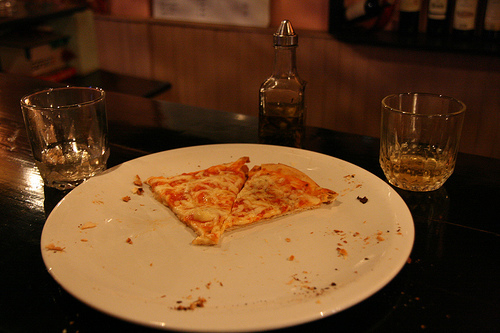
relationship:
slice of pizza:
[232, 159, 328, 229] [144, 153, 341, 247]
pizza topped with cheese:
[144, 153, 341, 247] [170, 181, 237, 222]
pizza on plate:
[144, 153, 341, 247] [31, 138, 420, 329]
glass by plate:
[359, 82, 475, 197] [31, 138, 420, 329]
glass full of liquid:
[359, 82, 475, 197] [379, 149, 456, 191]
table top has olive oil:
[4, 114, 499, 325] [255, 20, 314, 152]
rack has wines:
[331, 1, 498, 62] [342, 2, 500, 35]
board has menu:
[145, 3, 281, 36] [156, 2, 268, 22]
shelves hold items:
[13, 4, 167, 101] [5, 27, 85, 82]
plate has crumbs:
[31, 138, 420, 329] [285, 218, 362, 284]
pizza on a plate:
[144, 153, 341, 247] [31, 138, 420, 329]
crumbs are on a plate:
[285, 218, 362, 284] [31, 138, 420, 329]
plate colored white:
[31, 138, 420, 329] [102, 245, 163, 301]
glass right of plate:
[359, 82, 475, 197] [31, 138, 420, 329]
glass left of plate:
[20, 88, 118, 197] [31, 138, 420, 329]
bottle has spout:
[255, 20, 314, 152] [270, 21, 300, 46]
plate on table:
[31, 138, 420, 329] [4, 114, 499, 325]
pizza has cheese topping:
[144, 153, 341, 247] [170, 181, 237, 222]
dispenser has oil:
[255, 20, 314, 152] [259, 103, 310, 146]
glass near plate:
[359, 82, 475, 197] [31, 138, 420, 329]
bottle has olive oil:
[255, 20, 314, 152] [259, 103, 310, 146]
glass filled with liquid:
[359, 82, 475, 197] [379, 149, 456, 191]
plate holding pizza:
[31, 138, 420, 329] [144, 153, 341, 247]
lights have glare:
[5, 6, 117, 22] [18, 160, 52, 211]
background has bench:
[18, 9, 459, 151] [65, 54, 184, 105]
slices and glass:
[144, 153, 341, 247] [15, 79, 115, 194]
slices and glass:
[144, 153, 341, 247] [372, 85, 466, 196]